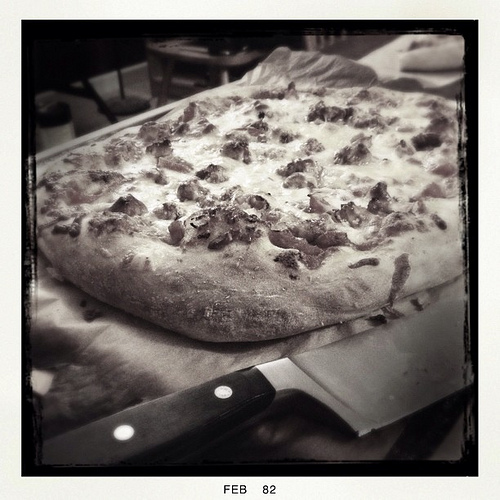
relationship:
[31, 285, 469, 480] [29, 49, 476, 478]
knife on board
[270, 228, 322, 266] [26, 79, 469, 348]
sausage on pizza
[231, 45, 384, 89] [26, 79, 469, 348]
paper under pizza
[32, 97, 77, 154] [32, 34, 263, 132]
basket against wall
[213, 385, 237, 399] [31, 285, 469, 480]
bolt in knife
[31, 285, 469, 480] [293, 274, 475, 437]
knife has a blade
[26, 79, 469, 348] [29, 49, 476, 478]
pizza on board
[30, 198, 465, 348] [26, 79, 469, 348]
crust on pizza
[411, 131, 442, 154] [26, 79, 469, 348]
olive on pizza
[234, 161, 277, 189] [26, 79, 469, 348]
cheese on pizza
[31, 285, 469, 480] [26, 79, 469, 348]
knife beside pizza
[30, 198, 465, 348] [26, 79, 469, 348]
crust of pizza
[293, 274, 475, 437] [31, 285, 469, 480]
blade on knife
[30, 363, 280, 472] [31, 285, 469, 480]
handle of knife